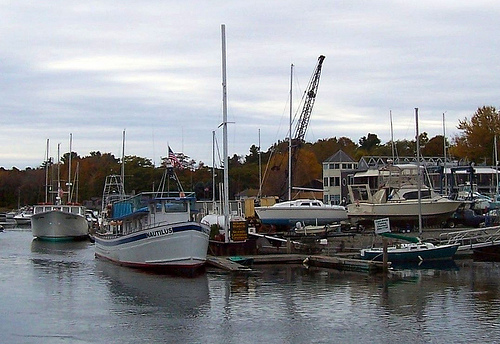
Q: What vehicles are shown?
A: Boats.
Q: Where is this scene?
A: Marina.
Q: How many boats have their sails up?
A: None.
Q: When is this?
A: Daytime.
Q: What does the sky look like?
A: Cloudy.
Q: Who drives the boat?
A: The captain.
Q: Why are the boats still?
A: The boats are docked.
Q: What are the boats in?
A: Water.